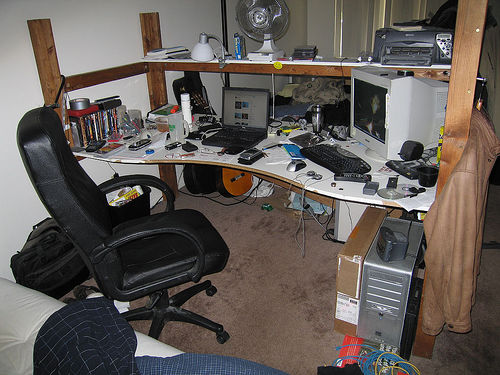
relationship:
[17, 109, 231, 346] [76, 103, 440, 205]
chair near desk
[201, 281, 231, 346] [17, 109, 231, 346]
wheels on chair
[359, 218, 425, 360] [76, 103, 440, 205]
computer tower under desk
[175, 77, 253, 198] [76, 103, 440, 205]
guitar behind desk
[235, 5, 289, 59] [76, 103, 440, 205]
fan on desk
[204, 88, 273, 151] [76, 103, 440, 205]
laptop on desk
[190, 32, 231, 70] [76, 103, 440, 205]
white lamp clipped on desk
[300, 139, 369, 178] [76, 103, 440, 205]
keyboard on desk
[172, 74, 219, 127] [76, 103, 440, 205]
black phone on desk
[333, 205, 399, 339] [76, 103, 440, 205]
cardboard box under desk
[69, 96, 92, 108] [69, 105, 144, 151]
duct tape roll on dvds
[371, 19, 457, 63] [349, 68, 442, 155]
printer over monitor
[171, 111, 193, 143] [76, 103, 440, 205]
white plastic cup on desk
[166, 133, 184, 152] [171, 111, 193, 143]
cell phone near white plastic cup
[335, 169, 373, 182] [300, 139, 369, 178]
black remote by keyboard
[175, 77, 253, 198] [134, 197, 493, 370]
guitar on carpet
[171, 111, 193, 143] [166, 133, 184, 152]
white plastic cup by cell phone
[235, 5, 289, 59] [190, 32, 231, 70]
fan beside white lamp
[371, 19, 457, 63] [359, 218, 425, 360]
printer for computer tower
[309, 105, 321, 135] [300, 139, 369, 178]
silver travel mug behind keyboard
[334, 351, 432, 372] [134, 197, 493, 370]
blue cords on carpet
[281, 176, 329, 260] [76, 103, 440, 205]
gray cords hanging from desk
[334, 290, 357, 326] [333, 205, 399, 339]
white label on cardboard box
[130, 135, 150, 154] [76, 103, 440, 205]
sony psp on desk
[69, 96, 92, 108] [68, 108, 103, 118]
duct tape roll on red book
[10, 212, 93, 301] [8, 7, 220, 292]
black bag against wall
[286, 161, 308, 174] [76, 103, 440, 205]
mouse on desk